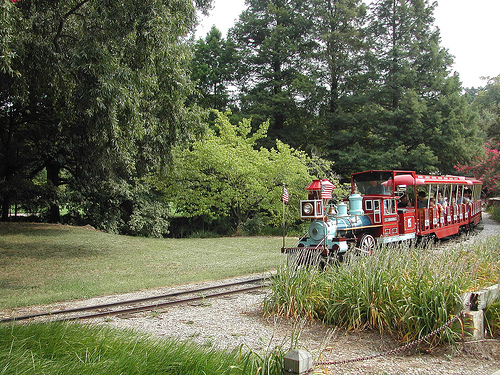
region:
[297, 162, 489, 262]
train on a track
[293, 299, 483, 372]
chain on two poles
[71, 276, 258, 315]
tracks for a train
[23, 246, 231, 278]
green grass by tracks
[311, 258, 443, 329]
tall green grasses by train tracks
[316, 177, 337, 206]
flag on a train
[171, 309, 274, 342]
dirt ground by train tracks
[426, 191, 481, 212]
passengers on a train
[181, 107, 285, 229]
green leaves on a tree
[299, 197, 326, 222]
front light on a train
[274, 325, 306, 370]
pat of a metal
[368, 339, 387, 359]
part of a chain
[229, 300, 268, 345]
part fio a ground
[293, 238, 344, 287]
part of a nappier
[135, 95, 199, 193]
poart iof a tree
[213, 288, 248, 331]
part of a bgrrpound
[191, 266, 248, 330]
part of a ground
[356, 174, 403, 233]
part of a train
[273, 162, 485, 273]
small red park train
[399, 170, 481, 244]
people riding a small train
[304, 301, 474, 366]
chain over a path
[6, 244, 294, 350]
small set of train tracks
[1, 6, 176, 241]
big tree with hanging branches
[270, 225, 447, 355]
tall grasses with yellowing spots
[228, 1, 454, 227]
three tall trees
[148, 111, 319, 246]
short light green tree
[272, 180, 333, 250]
two american flags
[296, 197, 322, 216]
small round headlight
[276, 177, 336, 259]
Flags on the side of the track.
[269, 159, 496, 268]
Train on the tracks.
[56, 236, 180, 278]
The grass is green.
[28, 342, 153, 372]
The grass is tall.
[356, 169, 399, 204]
Conductor driving the train.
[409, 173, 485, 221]
People riding in the train.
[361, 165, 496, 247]
The train is red.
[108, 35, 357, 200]
The trees are green.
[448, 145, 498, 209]
Red leaves on a tree.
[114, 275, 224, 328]
Gravel around the tracks.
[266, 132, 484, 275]
a miniature train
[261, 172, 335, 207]
two small US flags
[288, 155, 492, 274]
a miniature train with passengers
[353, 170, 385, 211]
an engineer driving the train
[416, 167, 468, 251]
red train carts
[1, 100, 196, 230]
trees with leaves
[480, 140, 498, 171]
branches with flowers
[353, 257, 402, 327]
tall grass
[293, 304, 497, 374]
chains connected two posts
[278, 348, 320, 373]
a wooden post that holds the other end of chain